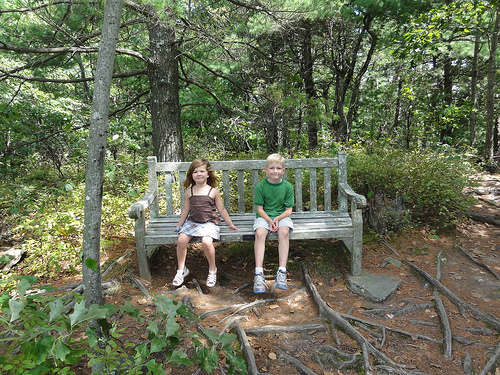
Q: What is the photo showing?
A: It is showing a forest.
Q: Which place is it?
A: It is a forest.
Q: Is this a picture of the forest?
A: Yes, it is showing the forest.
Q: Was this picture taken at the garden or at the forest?
A: It was taken at the forest.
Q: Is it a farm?
A: No, it is a forest.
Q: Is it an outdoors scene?
A: Yes, it is outdoors.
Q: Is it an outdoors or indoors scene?
A: It is outdoors.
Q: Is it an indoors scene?
A: No, it is outdoors.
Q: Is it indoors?
A: No, it is outdoors.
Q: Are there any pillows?
A: No, there are no pillows.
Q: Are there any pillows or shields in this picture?
A: No, there are no pillows or shields.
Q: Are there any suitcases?
A: No, there are no suitcases.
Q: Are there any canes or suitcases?
A: No, there are no suitcases or canes.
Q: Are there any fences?
A: No, there are no fences.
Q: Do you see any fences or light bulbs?
A: No, there are no fences or light bulbs.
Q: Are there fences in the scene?
A: No, there are no fences.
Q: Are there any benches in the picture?
A: Yes, there is a bench.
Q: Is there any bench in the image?
A: Yes, there is a bench.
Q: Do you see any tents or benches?
A: Yes, there is a bench.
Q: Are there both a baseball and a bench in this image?
A: No, there is a bench but no baseballs.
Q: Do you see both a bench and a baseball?
A: No, there is a bench but no baseballs.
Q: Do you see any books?
A: No, there are no books.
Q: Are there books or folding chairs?
A: No, there are no books or folding chairs.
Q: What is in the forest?
A: The bench is in the forest.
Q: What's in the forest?
A: The bench is in the forest.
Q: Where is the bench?
A: The bench is in the forest.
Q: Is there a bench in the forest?
A: Yes, there is a bench in the forest.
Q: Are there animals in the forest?
A: No, there is a bench in the forest.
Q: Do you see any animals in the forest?
A: No, there is a bench in the forest.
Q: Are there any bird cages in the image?
A: No, there are no bird cages.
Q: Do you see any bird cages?
A: No, there are no bird cages.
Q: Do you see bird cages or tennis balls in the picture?
A: No, there are no bird cages or tennis balls.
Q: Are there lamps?
A: No, there are no lamps.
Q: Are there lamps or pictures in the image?
A: No, there are no lamps or pictures.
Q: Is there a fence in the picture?
A: No, there are no fences.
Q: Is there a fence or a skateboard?
A: No, there are no fences or skateboards.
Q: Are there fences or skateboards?
A: No, there are no fences or skateboards.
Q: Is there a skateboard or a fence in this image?
A: No, there are no fences or skateboards.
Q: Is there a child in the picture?
A: Yes, there is a child.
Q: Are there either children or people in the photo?
A: Yes, there is a child.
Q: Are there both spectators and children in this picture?
A: No, there is a child but no spectators.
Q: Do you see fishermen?
A: No, there are no fishermen.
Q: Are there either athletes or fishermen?
A: No, there are no fishermen or athletes.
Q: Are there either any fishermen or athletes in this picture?
A: No, there are no fishermen or athletes.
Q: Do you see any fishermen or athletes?
A: No, there are no fishermen or athletes.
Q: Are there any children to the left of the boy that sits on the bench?
A: Yes, there is a child to the left of the boy.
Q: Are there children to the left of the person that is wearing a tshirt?
A: Yes, there is a child to the left of the boy.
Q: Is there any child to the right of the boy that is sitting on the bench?
A: No, the child is to the left of the boy.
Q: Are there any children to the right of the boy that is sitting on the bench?
A: No, the child is to the left of the boy.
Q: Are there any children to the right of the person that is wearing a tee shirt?
A: No, the child is to the left of the boy.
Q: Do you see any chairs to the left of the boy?
A: No, there is a child to the left of the boy.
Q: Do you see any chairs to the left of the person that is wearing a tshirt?
A: No, there is a child to the left of the boy.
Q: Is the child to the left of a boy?
A: Yes, the child is to the left of a boy.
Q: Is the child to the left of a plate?
A: No, the child is to the left of a boy.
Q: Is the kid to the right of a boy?
A: No, the kid is to the left of a boy.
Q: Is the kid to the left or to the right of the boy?
A: The kid is to the left of the boy.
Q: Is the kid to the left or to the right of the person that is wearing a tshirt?
A: The kid is to the left of the boy.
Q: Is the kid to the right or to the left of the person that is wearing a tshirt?
A: The kid is to the left of the boy.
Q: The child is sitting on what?
A: The child is sitting on the bench.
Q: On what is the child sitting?
A: The child is sitting on the bench.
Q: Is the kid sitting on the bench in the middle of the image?
A: Yes, the kid is sitting on the bench.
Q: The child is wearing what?
A: The child is wearing a sandal.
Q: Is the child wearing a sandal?
A: Yes, the child is wearing a sandal.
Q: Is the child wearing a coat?
A: No, the child is wearing a sandal.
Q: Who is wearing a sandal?
A: The kid is wearing a sandal.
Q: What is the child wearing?
A: The child is wearing a sandal.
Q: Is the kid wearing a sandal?
A: Yes, the kid is wearing a sandal.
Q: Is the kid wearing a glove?
A: No, the kid is wearing a sandal.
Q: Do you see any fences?
A: No, there are no fences.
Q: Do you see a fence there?
A: No, there are no fences.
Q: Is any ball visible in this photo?
A: No, there are no balls.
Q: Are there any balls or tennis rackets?
A: No, there are no balls or tennis rackets.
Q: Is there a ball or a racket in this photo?
A: No, there are no balls or rackets.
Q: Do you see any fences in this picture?
A: No, there are no fences.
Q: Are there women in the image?
A: No, there are no women.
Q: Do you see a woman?
A: No, there are no women.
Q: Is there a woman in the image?
A: No, there are no women.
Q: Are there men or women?
A: No, there are no women or men.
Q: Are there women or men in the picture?
A: No, there are no women or men.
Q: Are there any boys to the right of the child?
A: Yes, there is a boy to the right of the child.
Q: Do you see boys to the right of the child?
A: Yes, there is a boy to the right of the child.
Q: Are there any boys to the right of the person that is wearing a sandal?
A: Yes, there is a boy to the right of the child.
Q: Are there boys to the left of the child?
A: No, the boy is to the right of the child.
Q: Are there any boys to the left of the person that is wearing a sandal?
A: No, the boy is to the right of the child.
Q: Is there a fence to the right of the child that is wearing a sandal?
A: No, there is a boy to the right of the kid.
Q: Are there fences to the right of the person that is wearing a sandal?
A: No, there is a boy to the right of the kid.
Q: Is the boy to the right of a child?
A: Yes, the boy is to the right of a child.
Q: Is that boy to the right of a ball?
A: No, the boy is to the right of a child.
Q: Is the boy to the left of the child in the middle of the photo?
A: No, the boy is to the right of the child.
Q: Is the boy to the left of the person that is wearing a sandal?
A: No, the boy is to the right of the child.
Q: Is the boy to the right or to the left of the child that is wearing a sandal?
A: The boy is to the right of the kid.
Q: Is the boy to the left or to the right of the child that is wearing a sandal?
A: The boy is to the right of the kid.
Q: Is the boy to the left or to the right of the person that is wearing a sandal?
A: The boy is to the right of the kid.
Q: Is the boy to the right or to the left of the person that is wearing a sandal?
A: The boy is to the right of the kid.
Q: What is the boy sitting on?
A: The boy is sitting on the bench.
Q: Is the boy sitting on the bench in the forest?
A: Yes, the boy is sitting on the bench.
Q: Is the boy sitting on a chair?
A: No, the boy is sitting on the bench.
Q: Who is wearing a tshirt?
A: The boy is wearing a tshirt.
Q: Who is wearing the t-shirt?
A: The boy is wearing a tshirt.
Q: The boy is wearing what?
A: The boy is wearing a tshirt.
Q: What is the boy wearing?
A: The boy is wearing a tshirt.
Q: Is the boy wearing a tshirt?
A: Yes, the boy is wearing a tshirt.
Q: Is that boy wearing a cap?
A: No, the boy is wearing a tshirt.